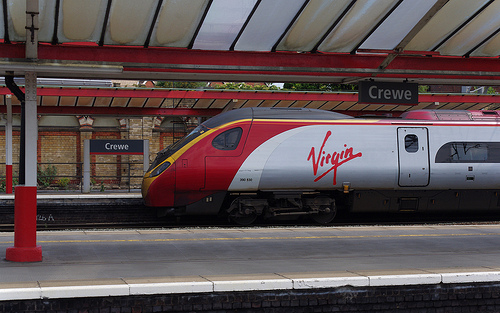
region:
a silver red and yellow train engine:
[135, 107, 498, 222]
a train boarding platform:
[0, 222, 499, 301]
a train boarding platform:
[0, 187, 145, 196]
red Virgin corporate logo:
[303, 128, 363, 187]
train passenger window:
[445, 142, 489, 162]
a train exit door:
[395, 124, 430, 187]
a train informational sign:
[355, 80, 420, 105]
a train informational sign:
[85, 137, 145, 157]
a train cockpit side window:
[214, 125, 241, 150]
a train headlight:
[149, 159, 169, 176]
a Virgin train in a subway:
[128, 96, 499, 221]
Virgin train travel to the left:
[127, 98, 499, 231]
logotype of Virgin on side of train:
[302, 126, 371, 193]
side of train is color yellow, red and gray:
[136, 116, 277, 206]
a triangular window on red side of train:
[205, 121, 247, 159]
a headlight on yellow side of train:
[145, 150, 175, 185]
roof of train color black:
[196, 99, 368, 120]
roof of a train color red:
[396, 100, 496, 120]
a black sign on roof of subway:
[353, 77, 428, 111]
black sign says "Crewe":
[352, 78, 426, 111]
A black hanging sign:
[356, 83, 419, 104]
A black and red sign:
[88, 138, 145, 155]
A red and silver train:
[141, 105, 496, 222]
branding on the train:
[303, 131, 362, 186]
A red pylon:
[2, 185, 51, 260]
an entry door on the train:
[391, 124, 429, 190]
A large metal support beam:
[23, 0, 39, 182]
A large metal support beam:
[4, 98, 14, 191]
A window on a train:
[441, 138, 499, 165]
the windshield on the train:
[166, 120, 203, 154]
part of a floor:
[291, 246, 315, 267]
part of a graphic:
[338, 153, 376, 178]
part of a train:
[274, 164, 323, 225]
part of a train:
[219, 148, 249, 207]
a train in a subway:
[118, 94, 498, 218]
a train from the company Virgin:
[130, 98, 497, 216]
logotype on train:
[300, 116, 370, 188]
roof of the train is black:
[126, 101, 499, 128]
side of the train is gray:
[268, 124, 498, 197]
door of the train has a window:
[395, 116, 433, 191]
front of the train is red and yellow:
[132, 103, 279, 220]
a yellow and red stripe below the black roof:
[304, 111, 499, 131]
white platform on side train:
[16, 213, 498, 293]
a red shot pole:
[3, 180, 48, 265]